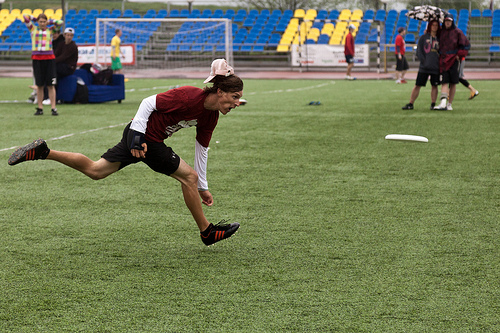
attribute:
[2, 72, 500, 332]
field — green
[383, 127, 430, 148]
frisbee — white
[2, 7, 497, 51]
chairs — blue, yellow, bright blue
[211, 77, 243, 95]
cap — brown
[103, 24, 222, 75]
net — white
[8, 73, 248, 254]
man — running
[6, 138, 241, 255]
shoes — red, black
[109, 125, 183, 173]
shorts — black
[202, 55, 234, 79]
hat — cream colored, pink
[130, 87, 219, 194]
shirt — white, brown, red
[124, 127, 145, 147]
glove — black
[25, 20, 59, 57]
sweater — colorful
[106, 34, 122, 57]
shirt — yellow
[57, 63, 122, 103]
sofa — blue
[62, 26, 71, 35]
hat — white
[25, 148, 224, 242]
stripes — red